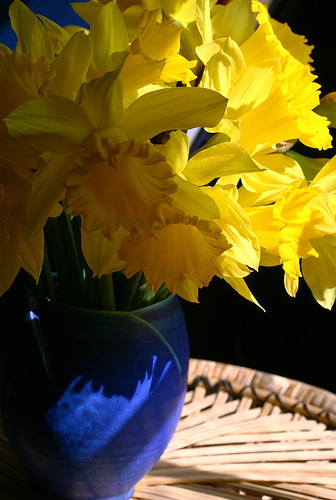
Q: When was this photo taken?
A: During the day.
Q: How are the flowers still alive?
A: Water in the vase.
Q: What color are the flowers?
A: Yellow.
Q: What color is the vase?
A: Blue.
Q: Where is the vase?
A: On the table.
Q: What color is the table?
A: Brown.